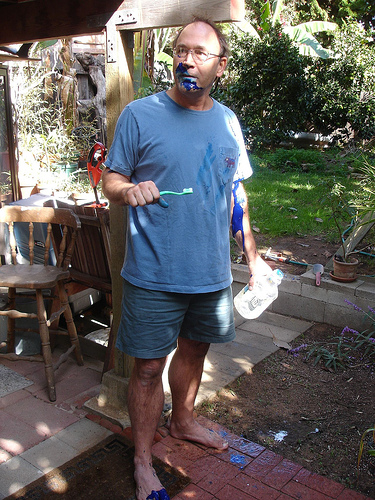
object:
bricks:
[250, 449, 272, 468]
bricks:
[224, 479, 260, 492]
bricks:
[281, 470, 320, 488]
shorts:
[113, 274, 236, 364]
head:
[170, 15, 229, 94]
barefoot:
[137, 454, 167, 498]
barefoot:
[171, 422, 229, 449]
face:
[170, 24, 219, 95]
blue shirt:
[108, 94, 254, 295]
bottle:
[227, 264, 285, 324]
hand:
[244, 248, 276, 298]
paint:
[220, 143, 241, 175]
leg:
[35, 285, 58, 402]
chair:
[0, 205, 86, 403]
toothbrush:
[162, 169, 194, 229]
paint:
[230, 451, 246, 468]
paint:
[230, 177, 245, 250]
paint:
[218, 430, 228, 436]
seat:
[0, 260, 76, 291]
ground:
[196, 322, 373, 499]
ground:
[249, 222, 373, 283]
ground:
[7, 433, 204, 498]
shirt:
[218, 142, 233, 173]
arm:
[227, 178, 277, 289]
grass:
[244, 150, 373, 251]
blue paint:
[171, 61, 206, 98]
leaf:
[291, 33, 337, 59]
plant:
[142, 1, 371, 62]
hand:
[247, 256, 273, 292]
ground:
[224, 140, 372, 293]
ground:
[0, 147, 373, 498]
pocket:
[219, 148, 244, 181]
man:
[100, 18, 271, 498]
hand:
[124, 179, 169, 213]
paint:
[144, 486, 169, 498]